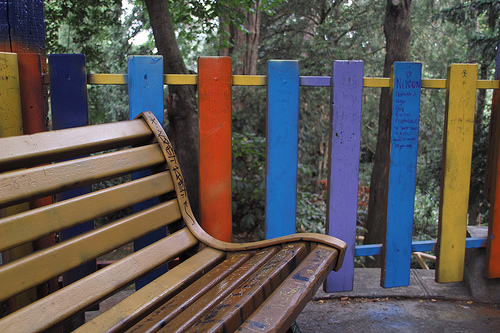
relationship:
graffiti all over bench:
[230, 242, 334, 333] [0, 109, 347, 330]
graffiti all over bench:
[201, 242, 301, 324] [0, 109, 347, 330]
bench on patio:
[0, 109, 347, 330] [6, 4, 496, 329]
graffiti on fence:
[391, 78, 421, 149] [3, 51, 498, 291]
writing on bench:
[140, 114, 332, 332] [0, 109, 347, 330]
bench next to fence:
[0, 109, 347, 330] [4, 37, 499, 317]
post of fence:
[436, 59, 478, 290] [3, 51, 498, 291]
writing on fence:
[391, 75, 422, 155] [188, 49, 482, 224]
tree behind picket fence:
[45, 0, 499, 268] [44, 47, 500, 314]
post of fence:
[436, 59, 478, 285] [46, 51, 499, 313]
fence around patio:
[46, 51, 499, 313] [381, 277, 467, 298]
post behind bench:
[436, 59, 478, 285] [0, 109, 347, 330]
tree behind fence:
[45, 0, 499, 268] [3, 51, 498, 291]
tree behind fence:
[145, 0, 198, 214] [3, 51, 498, 291]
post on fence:
[436, 59, 478, 285] [3, 51, 498, 291]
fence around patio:
[3, 51, 498, 291] [25, 254, 496, 331]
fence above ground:
[46, 51, 499, 313] [282, 264, 497, 329]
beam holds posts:
[43, 68, 498, 98] [42, 44, 498, 299]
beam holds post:
[43, 68, 498, 98] [436, 60, 482, 287]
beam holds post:
[43, 68, 498, 98] [383, 60, 425, 293]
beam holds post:
[43, 68, 498, 98] [320, 60, 363, 297]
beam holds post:
[43, 68, 498, 98] [262, 58, 299, 239]